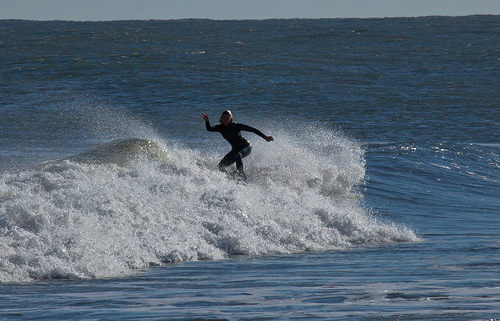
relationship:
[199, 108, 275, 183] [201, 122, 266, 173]
person wearing a wetsuit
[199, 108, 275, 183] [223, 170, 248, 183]
person standing on surfboard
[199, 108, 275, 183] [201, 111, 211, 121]
person has a hand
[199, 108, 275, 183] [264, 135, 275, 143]
person has a hand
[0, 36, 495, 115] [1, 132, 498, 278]
calm waters are behind waves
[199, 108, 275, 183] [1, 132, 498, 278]
person riding waves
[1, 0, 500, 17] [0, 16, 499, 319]
sky above water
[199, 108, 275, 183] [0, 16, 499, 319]
person surfing in water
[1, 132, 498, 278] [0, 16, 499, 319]
waves are in water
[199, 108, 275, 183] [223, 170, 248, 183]
person balancing on surfboard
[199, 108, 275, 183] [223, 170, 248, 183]
person on a surfboard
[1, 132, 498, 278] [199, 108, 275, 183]
waves are around person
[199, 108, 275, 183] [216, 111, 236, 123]
person has hair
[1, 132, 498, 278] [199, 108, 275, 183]
waves are churning around person